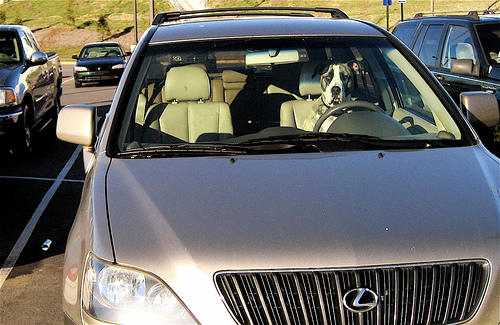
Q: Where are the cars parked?
A: In a lot.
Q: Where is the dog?
A: Behind steering wheel.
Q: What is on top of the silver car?
A: Luggage rack.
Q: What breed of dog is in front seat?
A: Great Dane.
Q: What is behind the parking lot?
A: Grass.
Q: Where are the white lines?
A: Parking lot spaces.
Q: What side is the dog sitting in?
A: Left side.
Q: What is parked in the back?
A: Black car.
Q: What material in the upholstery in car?
A: Leather.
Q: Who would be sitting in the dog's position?
A: Driver.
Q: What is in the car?
A: A dog.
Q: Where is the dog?
A: In the car.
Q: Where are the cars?
A: Parking lot.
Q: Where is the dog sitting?
A: In a car.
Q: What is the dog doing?
A: Sitting.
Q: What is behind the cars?
A: A hill.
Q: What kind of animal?
A: Dog.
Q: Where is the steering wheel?
A: In the car.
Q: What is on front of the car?
A: The grill.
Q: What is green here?
A: The grass.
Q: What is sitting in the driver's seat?
A: A dog.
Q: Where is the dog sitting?
A: The driver's seat.